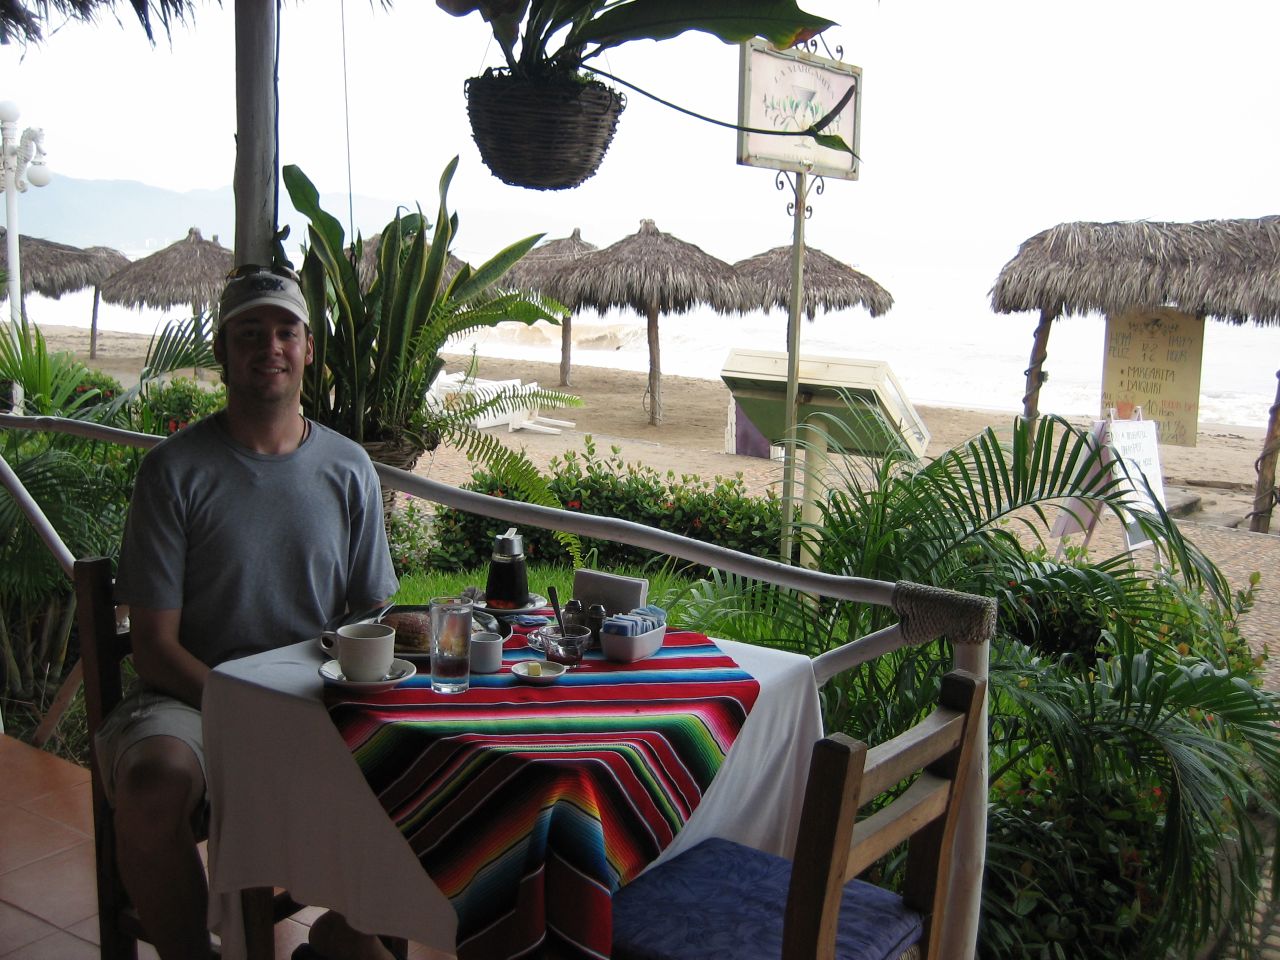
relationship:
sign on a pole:
[738, 30, 864, 183] [762, 150, 827, 568]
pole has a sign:
[767, 188, 821, 573] [739, 29, 868, 186]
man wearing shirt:
[81, 263, 415, 954] [106, 395, 415, 698]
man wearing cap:
[81, 263, 415, 959] [217, 272, 313, 331]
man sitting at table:
[81, 263, 415, 954] [183, 546, 843, 955]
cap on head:
[217, 272, 313, 331] [202, 250, 326, 407]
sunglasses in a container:
[225, 261, 303, 282] [480, 526, 533, 609]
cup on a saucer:
[319, 627, 412, 691] [320, 654, 426, 690]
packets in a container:
[604, 601, 662, 637] [602, 627, 666, 667]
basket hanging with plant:
[459, 66, 625, 194] [450, 0, 892, 166]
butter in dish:
[525, 658, 541, 674] [507, 649, 572, 694]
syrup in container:
[487, 554, 538, 612] [481, 526, 534, 608]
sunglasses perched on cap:
[218, 256, 309, 287] [220, 270, 322, 337]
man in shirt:
[81, 263, 415, 954] [127, 411, 406, 690]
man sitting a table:
[81, 263, 415, 959] [204, 599, 827, 957]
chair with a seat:
[615, 665, 986, 957] [610, 835, 928, 957]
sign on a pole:
[738, 30, 864, 183] [778, 172, 807, 565]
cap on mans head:
[216, 272, 312, 341] [213, 272, 317, 396]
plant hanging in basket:
[440, 2, 861, 199] [465, 56, 627, 193]